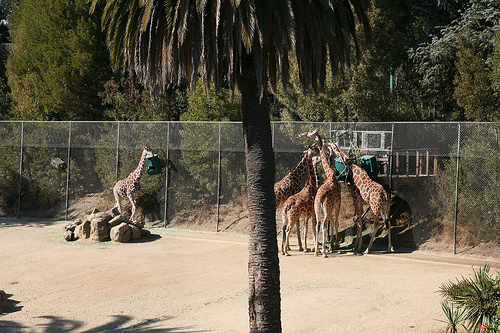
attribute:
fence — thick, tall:
[4, 113, 482, 260]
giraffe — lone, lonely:
[105, 147, 151, 217]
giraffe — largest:
[308, 130, 340, 250]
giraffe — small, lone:
[111, 147, 155, 223]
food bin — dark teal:
[319, 150, 378, 181]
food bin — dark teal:
[147, 152, 166, 172]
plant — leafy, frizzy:
[434, 268, 484, 319]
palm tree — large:
[111, 1, 361, 330]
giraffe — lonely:
[112, 149, 157, 217]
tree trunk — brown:
[240, 87, 285, 331]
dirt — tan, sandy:
[11, 224, 483, 322]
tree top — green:
[10, 11, 112, 121]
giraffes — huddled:
[229, 101, 410, 289]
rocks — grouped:
[58, 202, 169, 269]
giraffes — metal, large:
[41, 92, 392, 270]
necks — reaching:
[272, 137, 389, 182]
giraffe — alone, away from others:
[61, 118, 180, 251]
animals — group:
[39, 109, 414, 269]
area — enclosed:
[1, 96, 471, 330]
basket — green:
[139, 139, 171, 199]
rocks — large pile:
[61, 205, 159, 262]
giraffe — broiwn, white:
[91, 137, 159, 248]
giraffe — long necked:
[108, 107, 180, 237]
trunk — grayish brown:
[224, 169, 318, 329]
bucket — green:
[332, 133, 392, 184]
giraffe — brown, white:
[275, 82, 412, 288]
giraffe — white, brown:
[234, 103, 351, 285]